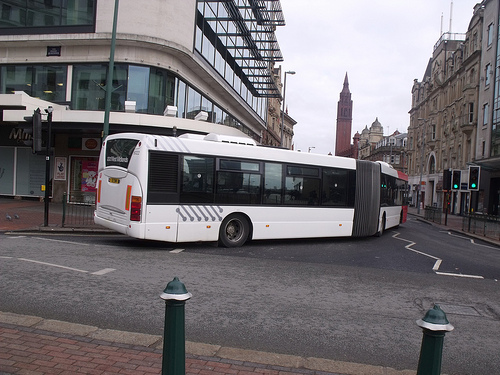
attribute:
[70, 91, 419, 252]
bus — long, white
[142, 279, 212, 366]
pole — green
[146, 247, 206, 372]
pole — green, silver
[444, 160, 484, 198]
lights — green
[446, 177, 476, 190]
lights — green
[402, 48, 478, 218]
building — tall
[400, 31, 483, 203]
building — brown, tall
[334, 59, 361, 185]
building — tall, brown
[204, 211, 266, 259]
wheel — rear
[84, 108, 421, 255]
bus — white, red, turning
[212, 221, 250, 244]
tire — black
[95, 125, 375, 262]
bus — gray, marked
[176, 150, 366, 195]
windows — large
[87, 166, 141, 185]
plate — yellow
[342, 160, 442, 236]
bus — red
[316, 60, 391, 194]
building — tall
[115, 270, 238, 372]
post — green, sticking out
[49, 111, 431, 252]
bus — white, turning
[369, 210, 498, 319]
road — white, marked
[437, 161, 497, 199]
stoplight — green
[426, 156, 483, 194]
stoplight — green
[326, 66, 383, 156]
skyscraper — pointy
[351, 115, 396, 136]
roof — domed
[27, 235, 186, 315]
road — white, marked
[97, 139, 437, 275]
bus — black, white, big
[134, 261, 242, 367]
poles — short, green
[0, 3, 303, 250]
building — big, beige, in the corner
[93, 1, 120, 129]
pole — large, green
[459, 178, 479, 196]
light — green, on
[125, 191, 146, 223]
back light — small, red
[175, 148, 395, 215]
windows — black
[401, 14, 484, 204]
building — big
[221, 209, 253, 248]
wheel — black, back wheel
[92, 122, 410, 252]
bus — white, city, long, double-length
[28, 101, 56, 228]
traffic light — black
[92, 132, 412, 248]
bus — large, white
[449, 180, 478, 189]
lights — green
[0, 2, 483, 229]
buildings — large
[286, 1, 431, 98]
sky — overcast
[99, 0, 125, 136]
pole — tall, green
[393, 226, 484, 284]
line — white, zigzag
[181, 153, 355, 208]
windows — side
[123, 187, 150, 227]
bus light — red rear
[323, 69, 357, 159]
building — tall brown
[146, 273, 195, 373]
pole — green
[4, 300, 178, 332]
sidewalk — brick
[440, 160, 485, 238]
traffic lights — two green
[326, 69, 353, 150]
tower — tall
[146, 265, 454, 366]
poles — two short green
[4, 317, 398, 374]
city sidewalk — red brick paved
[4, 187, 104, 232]
city sidewalk — red brick paved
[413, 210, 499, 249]
city sidewalk — red brick paved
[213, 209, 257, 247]
bus tire — black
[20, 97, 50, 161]
traffic signal — electronic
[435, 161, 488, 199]
traffic signal — electronic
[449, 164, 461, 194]
traffic signal — electronic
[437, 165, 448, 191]
traffic signal — electronic